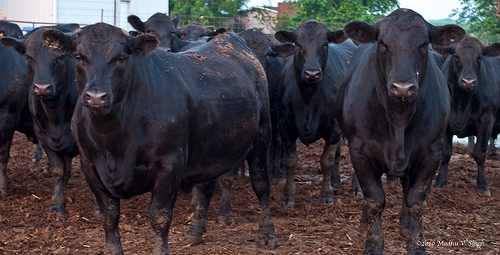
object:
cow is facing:
[42, 21, 285, 250]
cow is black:
[342, 6, 464, 252]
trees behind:
[170, 2, 232, 25]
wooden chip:
[340, 231, 353, 243]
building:
[239, 2, 281, 41]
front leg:
[150, 165, 176, 254]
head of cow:
[271, 9, 351, 86]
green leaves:
[303, 2, 339, 17]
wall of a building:
[1, 1, 177, 27]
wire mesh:
[177, 11, 276, 36]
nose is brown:
[392, 80, 419, 98]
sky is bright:
[401, 2, 458, 16]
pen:
[0, 13, 484, 245]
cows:
[453, 6, 485, 248]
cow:
[79, 11, 184, 243]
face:
[273, 20, 349, 77]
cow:
[278, 14, 346, 204]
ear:
[124, 28, 159, 55]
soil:
[306, 208, 362, 240]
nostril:
[97, 88, 107, 100]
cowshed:
[0, 3, 168, 33]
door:
[1, 0, 57, 30]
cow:
[42, 22, 65, 250]